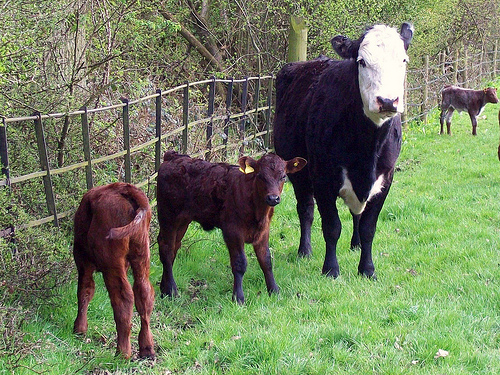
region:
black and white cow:
[278, 19, 425, 294]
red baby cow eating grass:
[67, 184, 164, 364]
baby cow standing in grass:
[157, 150, 304, 312]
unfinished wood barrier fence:
[2, 72, 280, 274]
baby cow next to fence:
[441, 85, 498, 134]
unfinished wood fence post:
[288, 14, 310, 65]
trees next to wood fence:
[3, 3, 127, 193]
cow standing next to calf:
[272, 24, 417, 279]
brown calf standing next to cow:
[157, 148, 301, 313]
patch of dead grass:
[6, 238, 69, 338]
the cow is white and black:
[267, 35, 444, 244]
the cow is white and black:
[247, 19, 392, 188]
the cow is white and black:
[297, 30, 417, 173]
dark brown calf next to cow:
[155, 148, 305, 304]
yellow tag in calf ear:
[242, 165, 254, 174]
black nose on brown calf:
[267, 196, 279, 205]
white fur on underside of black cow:
[340, 167, 386, 215]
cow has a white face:
[355, 23, 408, 127]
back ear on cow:
[329, 35, 359, 57]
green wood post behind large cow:
[285, 14, 311, 62]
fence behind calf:
[0, 74, 297, 266]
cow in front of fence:
[265, 23, 415, 280]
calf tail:
[107, 210, 149, 243]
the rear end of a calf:
[72, 181, 157, 358]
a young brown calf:
[155, 148, 307, 302]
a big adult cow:
[272, 22, 412, 279]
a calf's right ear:
[238, 155, 257, 174]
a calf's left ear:
[287, 156, 309, 173]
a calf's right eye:
[255, 171, 270, 183]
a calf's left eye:
[278, 171, 288, 181]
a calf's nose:
[265, 193, 281, 205]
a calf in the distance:
[439, 84, 499, 135]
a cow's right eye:
[357, 53, 367, 70]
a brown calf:
[58, 175, 149, 360]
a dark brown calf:
[155, 140, 310, 310]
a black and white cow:
[275, 15, 425, 281]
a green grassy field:
[5, 80, 495, 365]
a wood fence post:
[280, 5, 305, 65]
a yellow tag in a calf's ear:
[230, 155, 250, 170]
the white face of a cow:
[350, 20, 410, 130]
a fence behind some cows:
[0, 55, 287, 266]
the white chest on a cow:
[334, 165, 388, 220]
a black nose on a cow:
[376, 93, 399, 111]